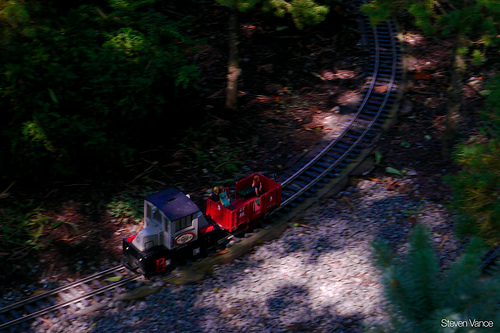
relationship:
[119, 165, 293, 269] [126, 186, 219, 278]
train has engine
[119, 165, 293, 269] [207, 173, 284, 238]
train has car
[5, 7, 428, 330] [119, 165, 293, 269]
tracks of train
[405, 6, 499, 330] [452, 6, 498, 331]
trees on right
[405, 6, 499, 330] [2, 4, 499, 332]
trees in photo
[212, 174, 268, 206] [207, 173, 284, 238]
people on car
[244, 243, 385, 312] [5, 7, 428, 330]
gravel to tracks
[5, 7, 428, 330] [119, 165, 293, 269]
tracks behind train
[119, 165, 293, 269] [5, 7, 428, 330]
train on track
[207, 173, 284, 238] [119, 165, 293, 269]
car on train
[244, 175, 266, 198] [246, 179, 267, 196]
little person sitting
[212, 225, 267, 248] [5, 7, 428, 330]
piece of track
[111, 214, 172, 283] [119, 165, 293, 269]
front of train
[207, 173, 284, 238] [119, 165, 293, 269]
car behind train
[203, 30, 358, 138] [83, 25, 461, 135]
shadow on ground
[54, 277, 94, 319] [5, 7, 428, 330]
light on track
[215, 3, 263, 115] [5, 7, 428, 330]
tree beside track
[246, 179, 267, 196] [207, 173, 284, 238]
sitting on car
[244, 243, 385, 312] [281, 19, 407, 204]
gravel beside rail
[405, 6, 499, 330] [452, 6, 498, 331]
plants on right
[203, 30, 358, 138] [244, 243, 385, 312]
shadow on gravel